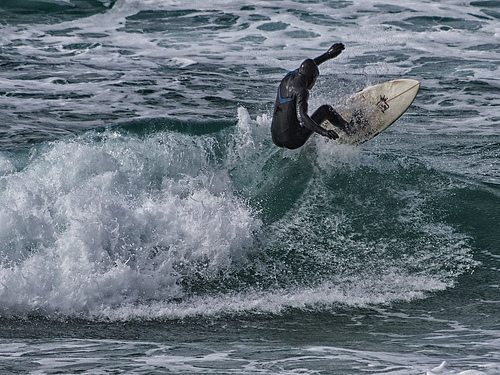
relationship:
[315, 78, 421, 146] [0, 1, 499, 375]
surfboard out of water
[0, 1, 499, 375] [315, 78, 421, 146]
water splashing on a surfboard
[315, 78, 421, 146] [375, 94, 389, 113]
surfboard has a mark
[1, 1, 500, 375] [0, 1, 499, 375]
foam on water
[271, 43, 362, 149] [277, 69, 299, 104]
wetsuit has a mark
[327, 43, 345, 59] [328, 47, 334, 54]
hand has a reflection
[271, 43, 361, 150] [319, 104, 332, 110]
surfer has a knee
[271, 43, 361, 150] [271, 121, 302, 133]
surfer has a waist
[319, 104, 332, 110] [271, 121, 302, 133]
knee above waist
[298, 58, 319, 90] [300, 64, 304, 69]
head has a reflection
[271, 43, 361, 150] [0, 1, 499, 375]
surfer surfing in water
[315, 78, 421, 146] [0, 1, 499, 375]
surfboard in water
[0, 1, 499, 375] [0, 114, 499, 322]
water has a wave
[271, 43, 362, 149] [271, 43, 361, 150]
wetsuit on surfer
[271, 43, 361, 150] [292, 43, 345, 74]
surfer has a left arm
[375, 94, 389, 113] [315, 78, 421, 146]
mark on surfboard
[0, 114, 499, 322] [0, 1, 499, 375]
wave in water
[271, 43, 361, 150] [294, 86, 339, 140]
surfer has a right arm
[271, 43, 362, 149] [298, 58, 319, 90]
wetsuit on head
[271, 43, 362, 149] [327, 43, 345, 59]
wetsuit on hand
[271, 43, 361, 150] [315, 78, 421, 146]
surfer on surfboard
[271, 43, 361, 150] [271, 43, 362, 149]
surfer in wetsuit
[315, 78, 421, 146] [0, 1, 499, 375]
surfboard on water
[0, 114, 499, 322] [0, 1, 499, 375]
wave on water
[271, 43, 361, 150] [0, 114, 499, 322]
surfer surfing on wave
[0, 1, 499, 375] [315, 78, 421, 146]
water spraying around surfboard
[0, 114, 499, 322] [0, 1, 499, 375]
wave rolling on water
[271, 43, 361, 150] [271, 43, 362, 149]
surfer wearing a wetsuit